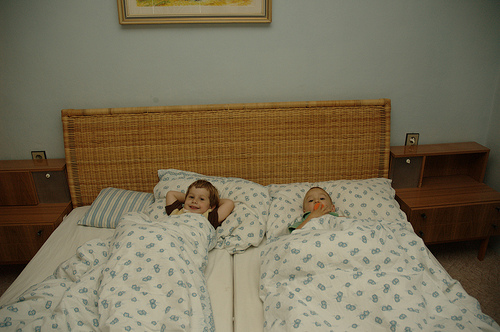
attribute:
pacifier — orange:
[312, 199, 329, 219]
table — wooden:
[383, 125, 496, 249]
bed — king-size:
[45, 109, 485, 330]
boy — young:
[164, 174, 248, 240]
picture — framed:
[109, 7, 282, 28]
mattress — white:
[226, 256, 260, 321]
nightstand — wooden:
[391, 135, 495, 252]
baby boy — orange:
[287, 183, 337, 235]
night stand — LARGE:
[390, 139, 494, 259]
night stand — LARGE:
[2, 158, 76, 266]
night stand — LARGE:
[5, 152, 73, 265]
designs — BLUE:
[122, 259, 175, 304]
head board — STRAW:
[64, 98, 392, 205]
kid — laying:
[164, 171, 232, 232]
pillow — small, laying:
[86, 190, 163, 233]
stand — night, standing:
[9, 148, 69, 265]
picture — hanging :
[109, 1, 292, 38]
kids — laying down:
[166, 165, 364, 239]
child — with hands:
[158, 174, 249, 254]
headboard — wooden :
[73, 112, 403, 191]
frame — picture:
[115, 2, 279, 24]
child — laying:
[298, 183, 324, 222]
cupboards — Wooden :
[407, 120, 497, 262]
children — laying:
[159, 166, 355, 227]